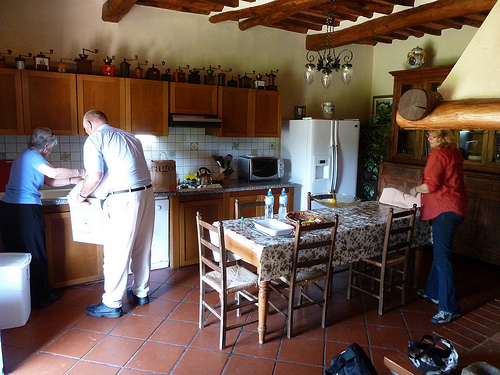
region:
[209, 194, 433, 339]
A wooden dining room table.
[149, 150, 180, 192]
A brown paper bag with a handle.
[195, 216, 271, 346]
A wooden chair.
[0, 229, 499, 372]
Red tiles on the ground.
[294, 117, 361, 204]
A white refrigerator.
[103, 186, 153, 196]
A black belt.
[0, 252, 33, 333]
A white trash bin.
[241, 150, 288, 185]
A microwave.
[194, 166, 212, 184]
A silver and black tea kettle.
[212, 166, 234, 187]
A wooden knife block.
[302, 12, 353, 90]
Hanging chandelier light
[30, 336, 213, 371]
Terra-cotta floor tiles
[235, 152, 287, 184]
Toaster oven on kitchen counter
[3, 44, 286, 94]
Collection of old coffee grinders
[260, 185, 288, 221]
Two water bottles on kitchen table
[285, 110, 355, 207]
White refrigerator with ice-maker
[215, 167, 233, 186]
Wood knife block with knives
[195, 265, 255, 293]
Wicker seat of dining chair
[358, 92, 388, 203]
Fake plant in corner of kitchen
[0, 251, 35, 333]
White plastic trash can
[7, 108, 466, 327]
three people in a kitchen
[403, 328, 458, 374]
a black and white helmet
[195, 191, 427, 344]
a table with five wooden chairs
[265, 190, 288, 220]
two bottles of water on a table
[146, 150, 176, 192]
a brown grocery bag on a counter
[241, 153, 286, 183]
a silver microwave on a counter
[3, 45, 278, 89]
a collection of coffee grinders on a shelf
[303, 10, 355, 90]
a chandelier hanging from the ceiling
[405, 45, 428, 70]
a decorative jar on a shelf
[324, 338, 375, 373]
a black bag on the floor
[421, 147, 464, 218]
a red button-down shirt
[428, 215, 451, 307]
a pair of blue jeans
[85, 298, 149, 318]
a pair of black sneakers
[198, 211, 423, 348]
a small table with wooden chairs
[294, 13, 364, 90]
a black chandelier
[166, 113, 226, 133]
an over the stove top light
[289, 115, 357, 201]
a two door upright refrigerator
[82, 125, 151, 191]
a light color long sleeve shirt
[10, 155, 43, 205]
a blue short sleeve shirt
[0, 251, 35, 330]
a white knee-high trashcan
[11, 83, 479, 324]
Three people in a kitchen.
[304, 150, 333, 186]
Ice maker/water dispenser on refrigerator door.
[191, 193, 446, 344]
A long square kitchen table.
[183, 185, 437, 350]
Six wooden chairs around table.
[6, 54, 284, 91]
A collection of coffe grinders.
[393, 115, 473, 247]
A woman with blonde hair.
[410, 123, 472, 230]
Woman wearing a long sleeve shirt.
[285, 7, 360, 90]
Chandelier hanging from rafters.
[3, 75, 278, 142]
Brown wood overhead cabinets